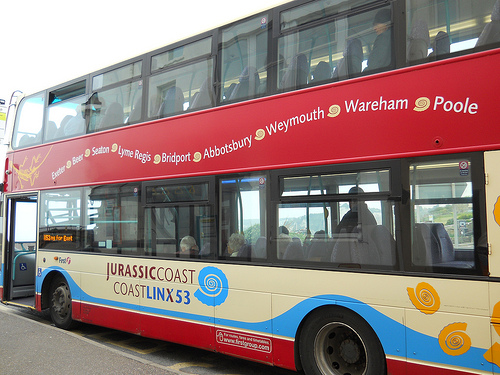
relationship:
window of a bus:
[214, 172, 271, 262] [0, 0, 500, 375]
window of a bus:
[274, 170, 396, 267] [0, 0, 500, 375]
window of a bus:
[405, 154, 475, 271] [0, 0, 500, 375]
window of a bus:
[141, 176, 212, 257] [0, 0, 500, 375]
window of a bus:
[38, 189, 83, 249] [0, 0, 500, 375]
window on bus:
[215, 12, 266, 101] [0, 0, 500, 375]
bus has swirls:
[0, 0, 500, 375] [409, 279, 440, 316]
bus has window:
[2, 39, 488, 370] [41, 147, 493, 280]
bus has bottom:
[0, 0, 500, 375] [79, 286, 498, 355]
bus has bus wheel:
[0, 0, 500, 375] [37, 270, 78, 332]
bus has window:
[0, 0, 500, 375] [267, 171, 398, 202]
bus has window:
[0, 0, 500, 375] [277, 200, 397, 266]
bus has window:
[0, 0, 500, 375] [407, 161, 473, 269]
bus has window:
[0, 0, 500, 375] [139, 176, 216, 211]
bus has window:
[0, 0, 500, 375] [40, 180, 145, 255]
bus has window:
[0, 0, 500, 375] [102, 157, 255, 293]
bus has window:
[0, 0, 500, 375] [220, 171, 265, 261]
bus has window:
[0, 0, 500, 375] [215, 12, 266, 101]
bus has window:
[0, 0, 500, 375] [146, 60, 214, 117]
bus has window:
[0, 0, 500, 375] [88, 79, 145, 130]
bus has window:
[0, 0, 500, 375] [11, 90, 44, 149]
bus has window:
[0, 0, 500, 375] [141, 22, 216, 127]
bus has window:
[0, 0, 500, 375] [141, 173, 216, 260]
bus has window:
[0, 0, 500, 375] [399, 146, 488, 288]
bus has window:
[0, 0, 500, 375] [267, 158, 398, 277]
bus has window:
[0, 0, 500, 375] [211, 169, 276, 263]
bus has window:
[0, 0, 500, 375] [198, 33, 338, 91]